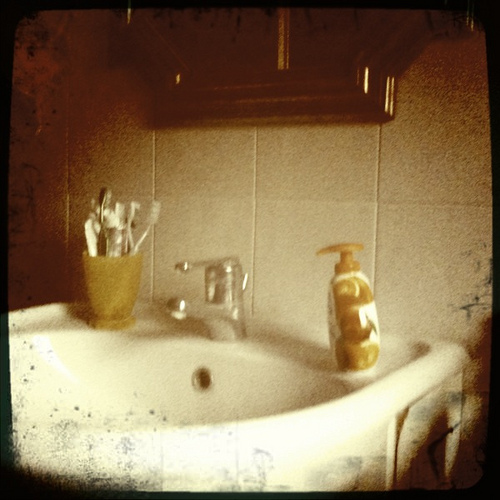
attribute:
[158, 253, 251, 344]
faucet — silver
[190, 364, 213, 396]
hole — empty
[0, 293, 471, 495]
bathroom sink — white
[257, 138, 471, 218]
wall — curved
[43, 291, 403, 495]
wink — white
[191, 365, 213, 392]
hole — round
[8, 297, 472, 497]
sink — white, porcelain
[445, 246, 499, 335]
marks — dark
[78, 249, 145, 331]
toothbrush holder — yellow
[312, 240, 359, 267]
dispenser — plastic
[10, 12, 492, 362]
wall — light color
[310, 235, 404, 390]
soap — plastic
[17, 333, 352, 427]
sinkbowl — white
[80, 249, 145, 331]
cup — maize-colored, bathroom